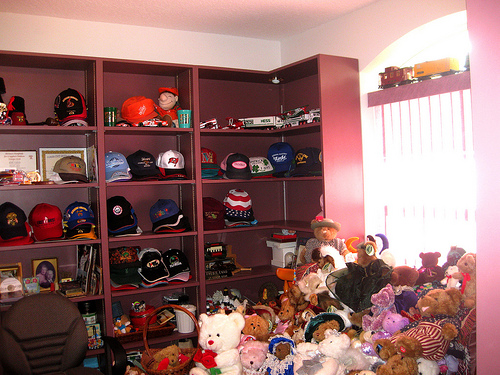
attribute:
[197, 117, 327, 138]
shelf — top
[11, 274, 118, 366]
chair — black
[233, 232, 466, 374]
stuffed animals — collection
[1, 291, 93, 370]
chair — black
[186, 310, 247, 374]
teddy bear — white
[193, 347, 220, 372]
roses — red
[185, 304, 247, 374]
bear — white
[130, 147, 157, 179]
hat — black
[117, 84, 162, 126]
hat — orange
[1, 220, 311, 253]
shelf — filled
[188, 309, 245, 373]
bear — White 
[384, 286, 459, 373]
bear — white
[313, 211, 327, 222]
flower — pink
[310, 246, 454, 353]
toys — stuffed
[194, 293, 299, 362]
toys — stuffed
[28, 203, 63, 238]
hat — red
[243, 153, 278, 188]
hat — black, pink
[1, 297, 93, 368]
chair — black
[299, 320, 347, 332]
doll — Dora the Explorer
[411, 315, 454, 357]
clothing — patriotic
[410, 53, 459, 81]
train car — yellow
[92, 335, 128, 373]
armrest — black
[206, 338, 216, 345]
nose — red